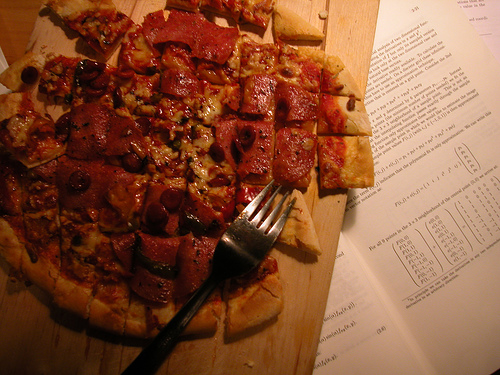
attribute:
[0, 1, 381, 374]
board — partition, light brown, wooden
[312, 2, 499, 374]
paper — white, book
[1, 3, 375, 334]
food — round, squared, cut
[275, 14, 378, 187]
crust — brown, cooked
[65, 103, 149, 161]
pepperoni — red, sliced, cut, bite size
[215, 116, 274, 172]
pepperoni — red, sliced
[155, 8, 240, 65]
pepperoni — red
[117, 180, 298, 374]
fork — metal, silver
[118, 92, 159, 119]
susage — brown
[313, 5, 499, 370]
text — black, numbers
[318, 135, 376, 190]
squares — small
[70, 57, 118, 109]
squares — small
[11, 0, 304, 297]
cheese — melted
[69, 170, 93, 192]
olives — black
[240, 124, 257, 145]
olives — black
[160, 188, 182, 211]
olives — black